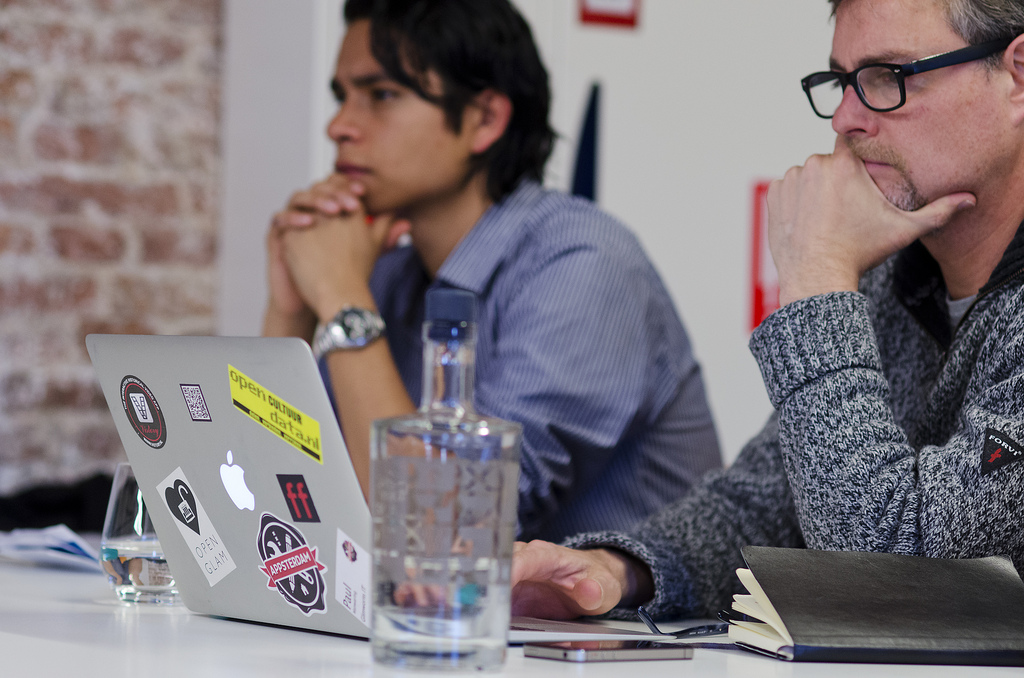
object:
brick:
[49, 219, 128, 254]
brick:
[132, 222, 212, 263]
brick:
[116, 270, 159, 307]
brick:
[2, 271, 87, 305]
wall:
[0, 3, 225, 494]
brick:
[14, 373, 90, 405]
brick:
[2, 424, 60, 472]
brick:
[57, 32, 135, 67]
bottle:
[365, 291, 517, 670]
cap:
[425, 290, 471, 320]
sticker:
[230, 373, 321, 451]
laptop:
[85, 332, 676, 642]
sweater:
[562, 232, 1020, 628]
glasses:
[802, 42, 1018, 114]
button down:
[318, 179, 726, 538]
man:
[703, 5, 1020, 619]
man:
[239, 7, 726, 550]